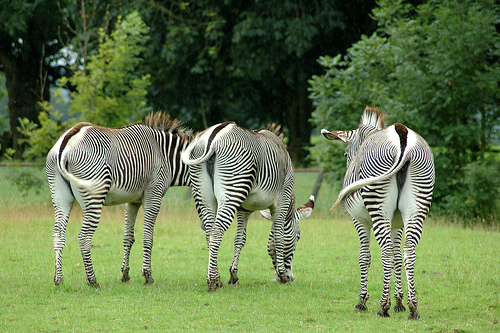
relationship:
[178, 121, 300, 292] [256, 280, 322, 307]
zebra eating grass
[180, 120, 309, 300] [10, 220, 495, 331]
zebra grazing on grass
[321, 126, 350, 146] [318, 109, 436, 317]
left ear of zebra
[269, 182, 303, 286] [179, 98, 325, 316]
arm of zebra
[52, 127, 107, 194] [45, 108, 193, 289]
tail of zebra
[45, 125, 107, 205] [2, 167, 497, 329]
zebra butt in field